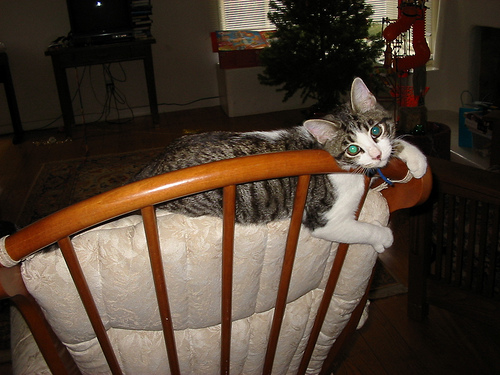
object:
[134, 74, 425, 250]
cat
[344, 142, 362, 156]
eye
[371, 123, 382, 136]
eye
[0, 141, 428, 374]
chair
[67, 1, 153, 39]
tv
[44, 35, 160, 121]
stand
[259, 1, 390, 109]
christmas tree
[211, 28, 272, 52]
wrapped gift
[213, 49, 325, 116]
table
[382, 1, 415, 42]
stocking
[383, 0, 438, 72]
stocking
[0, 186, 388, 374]
cushion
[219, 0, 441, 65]
window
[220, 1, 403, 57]
mini blinds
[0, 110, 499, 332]
area rug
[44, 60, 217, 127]
cords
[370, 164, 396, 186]
collar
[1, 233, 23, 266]
strap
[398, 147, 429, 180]
paw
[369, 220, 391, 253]
paw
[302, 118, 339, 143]
ear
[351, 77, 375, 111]
ear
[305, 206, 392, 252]
front leg